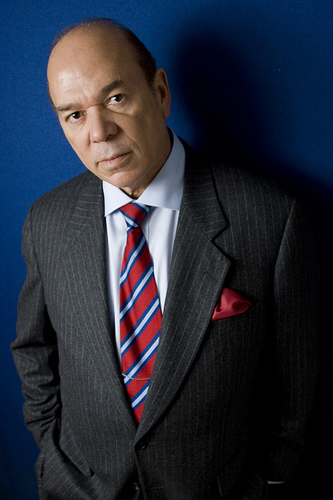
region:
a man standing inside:
[35, 28, 223, 215]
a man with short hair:
[40, 10, 200, 189]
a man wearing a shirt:
[36, 15, 263, 366]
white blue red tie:
[118, 229, 230, 436]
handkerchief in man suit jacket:
[206, 284, 247, 326]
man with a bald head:
[38, 38, 117, 91]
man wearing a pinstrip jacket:
[25, 179, 294, 348]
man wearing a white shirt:
[74, 160, 183, 264]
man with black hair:
[118, 25, 162, 90]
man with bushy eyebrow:
[93, 79, 122, 92]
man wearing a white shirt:
[88, 186, 188, 236]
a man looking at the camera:
[7, 7, 330, 497]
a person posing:
[3, 9, 331, 498]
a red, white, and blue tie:
[98, 190, 176, 434]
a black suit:
[17, 97, 319, 498]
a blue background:
[3, 4, 328, 406]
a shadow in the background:
[146, 3, 307, 171]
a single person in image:
[2, 2, 332, 493]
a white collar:
[74, 129, 205, 227]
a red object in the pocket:
[206, 269, 255, 332]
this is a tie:
[117, 205, 159, 325]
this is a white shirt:
[151, 222, 159, 246]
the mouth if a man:
[94, 147, 129, 171]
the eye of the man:
[96, 89, 127, 108]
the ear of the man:
[153, 68, 172, 122]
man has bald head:
[34, 13, 128, 86]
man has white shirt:
[50, 153, 171, 381]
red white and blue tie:
[93, 188, 176, 429]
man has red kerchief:
[217, 257, 242, 332]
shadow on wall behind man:
[200, 37, 327, 157]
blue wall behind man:
[291, 30, 326, 161]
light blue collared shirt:
[87, 120, 183, 277]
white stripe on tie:
[109, 212, 174, 340]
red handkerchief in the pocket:
[206, 282, 257, 324]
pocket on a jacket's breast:
[208, 309, 250, 357]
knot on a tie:
[115, 197, 153, 229]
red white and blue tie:
[112, 197, 165, 423]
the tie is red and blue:
[110, 197, 168, 422]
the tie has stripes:
[110, 199, 171, 427]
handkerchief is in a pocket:
[205, 277, 253, 332]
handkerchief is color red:
[208, 284, 251, 320]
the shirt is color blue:
[96, 147, 191, 429]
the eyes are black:
[58, 88, 129, 123]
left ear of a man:
[150, 63, 175, 118]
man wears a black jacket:
[4, 15, 327, 498]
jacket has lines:
[50, 292, 115, 444]